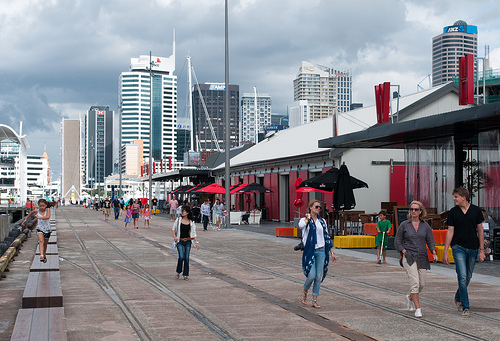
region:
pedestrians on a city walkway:
[10, 43, 482, 328]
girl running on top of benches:
[12, 180, 82, 311]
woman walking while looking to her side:
[160, 200, 212, 285]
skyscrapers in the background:
[71, 42, 371, 193]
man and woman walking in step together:
[372, 170, 483, 325]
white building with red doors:
[211, 75, 443, 220]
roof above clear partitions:
[355, 111, 490, 266]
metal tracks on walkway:
[55, 170, 415, 330]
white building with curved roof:
[0, 110, 40, 215]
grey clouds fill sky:
[38, 10, 399, 60]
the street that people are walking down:
[37, 195, 497, 339]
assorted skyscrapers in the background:
[45, 27, 486, 175]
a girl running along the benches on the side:
[31, 198, 57, 261]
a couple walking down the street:
[388, 185, 490, 325]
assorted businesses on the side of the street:
[157, 67, 499, 279]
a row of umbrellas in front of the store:
[182, 174, 269, 198]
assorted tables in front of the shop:
[283, 207, 472, 265]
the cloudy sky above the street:
[4, 4, 454, 83]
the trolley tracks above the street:
[63, 197, 221, 337]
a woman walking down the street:
[290, 198, 339, 310]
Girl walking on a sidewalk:
[162, 191, 202, 288]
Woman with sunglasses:
[291, 199, 363, 339]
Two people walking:
[391, 177, 497, 334]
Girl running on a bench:
[29, 196, 68, 269]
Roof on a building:
[214, 103, 371, 209]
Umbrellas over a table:
[176, 173, 368, 217]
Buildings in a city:
[58, 90, 213, 210]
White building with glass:
[114, 76, 189, 188]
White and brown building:
[50, 111, 98, 203]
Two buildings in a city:
[196, 81, 282, 186]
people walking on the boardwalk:
[38, 180, 433, 315]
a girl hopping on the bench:
[30, 192, 66, 264]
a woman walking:
[158, 196, 223, 278]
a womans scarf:
[293, 230, 328, 278]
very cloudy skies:
[26, 17, 126, 60]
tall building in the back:
[62, 32, 381, 118]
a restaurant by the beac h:
[132, 120, 356, 216]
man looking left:
[447, 190, 494, 329]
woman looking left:
[165, 203, 219, 288]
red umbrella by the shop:
[201, 177, 226, 204]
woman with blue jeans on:
[295, 192, 344, 305]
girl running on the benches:
[20, 185, 60, 289]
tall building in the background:
[104, 13, 193, 183]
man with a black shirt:
[433, 184, 491, 256]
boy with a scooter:
[360, 202, 401, 269]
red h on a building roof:
[446, 50, 481, 122]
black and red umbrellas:
[217, 172, 275, 227]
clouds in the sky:
[0, 82, 85, 155]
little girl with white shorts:
[140, 192, 158, 228]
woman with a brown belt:
[167, 227, 202, 248]